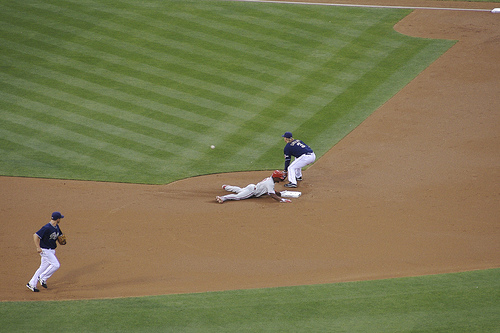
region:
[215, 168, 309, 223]
player on the ground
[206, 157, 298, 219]
player on the ground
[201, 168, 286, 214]
player on the ground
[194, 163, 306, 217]
player on the ground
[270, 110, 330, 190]
person at second base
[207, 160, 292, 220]
person on the ground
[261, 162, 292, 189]
red helmet on person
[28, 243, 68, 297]
white pants on player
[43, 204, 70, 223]
blue hat on man's head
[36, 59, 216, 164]
pattern on the ground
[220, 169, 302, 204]
man in red sliding to base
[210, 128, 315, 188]
ball is coming at man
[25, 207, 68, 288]
man is watching the ball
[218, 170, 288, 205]
red helmet on man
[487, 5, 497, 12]
base in the far right corner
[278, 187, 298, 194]
base man is sliding onto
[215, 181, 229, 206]
red and white shoes on man in center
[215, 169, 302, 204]
a baseball player sliding into base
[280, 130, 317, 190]
a baseball player crouching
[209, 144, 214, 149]
a white baseball in flight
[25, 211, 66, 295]
a baseball player running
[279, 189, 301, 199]
a white baseball base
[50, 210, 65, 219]
a blue baseball cap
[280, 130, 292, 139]
a blue baseball cap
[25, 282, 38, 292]
a black and white athletic shoe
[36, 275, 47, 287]
a black and white athletic shoe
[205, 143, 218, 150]
baseball flying through the air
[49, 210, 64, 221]
black cap player is wearing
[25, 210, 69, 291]
baseball player is running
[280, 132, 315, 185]
player reaching to catch the baseball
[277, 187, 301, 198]
white baseball plate on the ground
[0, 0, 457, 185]
green grass of the baseball field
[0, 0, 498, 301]
dirt on the baseball field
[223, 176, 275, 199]
white uniform baseball player is wearing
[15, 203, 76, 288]
the player is running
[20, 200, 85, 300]
the player is running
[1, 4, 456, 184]
neatly cut green grass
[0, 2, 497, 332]
players on baseball infield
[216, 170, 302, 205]
player laying before base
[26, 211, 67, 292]
running player in white pants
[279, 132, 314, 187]
bent player in blue shirt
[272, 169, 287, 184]
red helmet on head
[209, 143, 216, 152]
baseball in mid air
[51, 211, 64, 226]
hat on player's head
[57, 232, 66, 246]
glove on player's hand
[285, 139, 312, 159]
blue shirt with white number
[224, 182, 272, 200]
black baseball uniform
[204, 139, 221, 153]
white ball in the grass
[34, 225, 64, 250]
blue and white shirt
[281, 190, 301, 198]
white baseball base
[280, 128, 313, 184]
man standing on the sand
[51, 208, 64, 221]
Player blue cap left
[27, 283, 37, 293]
black shoes of the right foot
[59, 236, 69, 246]
brown baseball glove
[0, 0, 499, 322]
athletes playing a game of baseball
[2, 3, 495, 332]
green and brown baseball field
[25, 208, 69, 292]
man running on a field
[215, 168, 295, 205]
baseball player on the ground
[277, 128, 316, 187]
baseball player bending over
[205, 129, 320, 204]
baseball player bending over to catch a ball